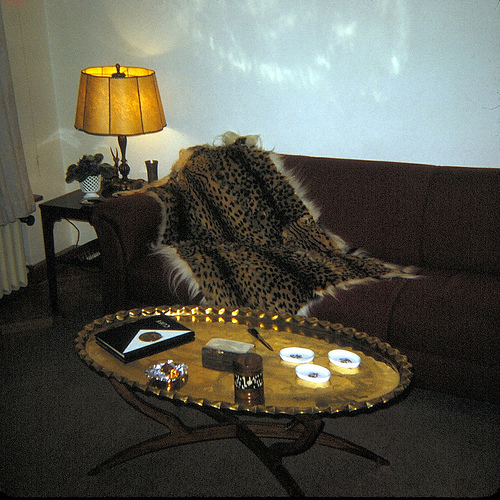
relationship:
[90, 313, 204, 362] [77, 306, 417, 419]
book on table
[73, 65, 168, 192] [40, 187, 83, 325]
light on stand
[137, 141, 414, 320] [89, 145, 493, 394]
fur on couch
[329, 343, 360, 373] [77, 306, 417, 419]
bowl on table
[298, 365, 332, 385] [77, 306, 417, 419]
bowl on table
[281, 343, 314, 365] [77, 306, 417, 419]
bowl on table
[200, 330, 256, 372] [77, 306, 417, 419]
box on table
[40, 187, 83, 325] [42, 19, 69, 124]
stand in corner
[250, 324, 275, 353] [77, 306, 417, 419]
pen on table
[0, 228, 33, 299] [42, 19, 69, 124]
radiator in corner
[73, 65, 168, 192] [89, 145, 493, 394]
light by couch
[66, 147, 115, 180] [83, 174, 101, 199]
plant in vase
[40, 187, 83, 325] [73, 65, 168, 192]
stand supports light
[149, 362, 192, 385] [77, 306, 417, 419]
dish on table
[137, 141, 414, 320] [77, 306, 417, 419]
fur on table